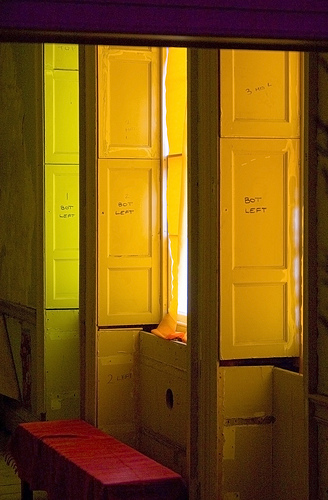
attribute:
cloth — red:
[32, 428, 81, 444]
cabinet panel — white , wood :
[93, 155, 165, 332]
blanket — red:
[7, 415, 182, 499]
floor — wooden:
[2, 457, 21, 499]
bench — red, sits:
[15, 418, 188, 499]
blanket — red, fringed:
[6, 416, 187, 493]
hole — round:
[164, 385, 174, 410]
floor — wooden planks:
[1, 453, 46, 497]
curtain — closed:
[150, 47, 192, 345]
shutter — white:
[96, 159, 162, 329]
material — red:
[149, 313, 185, 344]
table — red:
[4, 418, 190, 499]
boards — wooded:
[0, 452, 50, 499]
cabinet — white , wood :
[39, 159, 89, 310]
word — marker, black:
[54, 197, 80, 223]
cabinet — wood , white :
[44, 44, 80, 165]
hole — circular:
[163, 386, 175, 412]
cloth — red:
[0, 417, 183, 498]